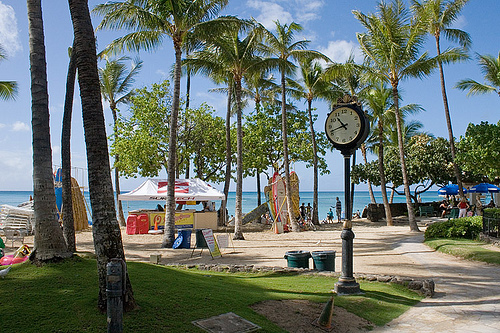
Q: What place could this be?
A: It is a park.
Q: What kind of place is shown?
A: It is a park.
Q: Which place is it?
A: It is a park.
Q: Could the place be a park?
A: Yes, it is a park.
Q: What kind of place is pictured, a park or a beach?
A: It is a park.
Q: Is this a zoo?
A: No, it is a park.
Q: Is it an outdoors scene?
A: Yes, it is outdoors.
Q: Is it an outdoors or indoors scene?
A: It is outdoors.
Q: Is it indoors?
A: No, it is outdoors.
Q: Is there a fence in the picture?
A: No, there are no fences.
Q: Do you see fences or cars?
A: No, there are no fences or cars.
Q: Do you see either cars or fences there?
A: No, there are no fences or cars.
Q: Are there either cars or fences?
A: No, there are no fences or cars.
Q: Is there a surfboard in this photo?
A: Yes, there is a surfboard.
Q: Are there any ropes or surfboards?
A: Yes, there is a surfboard.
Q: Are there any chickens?
A: No, there are no chickens.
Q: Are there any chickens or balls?
A: No, there are no chickens or balls.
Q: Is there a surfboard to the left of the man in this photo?
A: Yes, there is a surfboard to the left of the man.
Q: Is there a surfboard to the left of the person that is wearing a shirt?
A: Yes, there is a surfboard to the left of the man.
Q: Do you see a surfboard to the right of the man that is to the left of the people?
A: No, the surfboard is to the left of the man.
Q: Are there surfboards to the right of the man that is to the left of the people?
A: No, the surfboard is to the left of the man.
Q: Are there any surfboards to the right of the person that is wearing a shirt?
A: No, the surfboard is to the left of the man.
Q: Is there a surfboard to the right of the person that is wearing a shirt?
A: No, the surfboard is to the left of the man.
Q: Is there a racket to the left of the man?
A: No, there is a surfboard to the left of the man.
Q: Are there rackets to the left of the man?
A: No, there is a surfboard to the left of the man.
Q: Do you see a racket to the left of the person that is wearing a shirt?
A: No, there is a surfboard to the left of the man.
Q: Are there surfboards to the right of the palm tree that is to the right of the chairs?
A: Yes, there is a surfboard to the right of the palm tree.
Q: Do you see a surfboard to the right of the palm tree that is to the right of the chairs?
A: Yes, there is a surfboard to the right of the palm tree.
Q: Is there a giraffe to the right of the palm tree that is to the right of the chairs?
A: No, there is a surfboard to the right of the palm tree.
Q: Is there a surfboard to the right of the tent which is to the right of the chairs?
A: Yes, there is a surfboard to the right of the tent.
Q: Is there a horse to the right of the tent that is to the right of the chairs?
A: No, there is a surfboard to the right of the tent.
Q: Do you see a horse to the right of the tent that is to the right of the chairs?
A: No, there is a surfboard to the right of the tent.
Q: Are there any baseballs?
A: No, there are no baseballs.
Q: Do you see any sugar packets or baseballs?
A: No, there are no baseballs or sugar packets.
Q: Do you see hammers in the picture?
A: No, there are no hammers.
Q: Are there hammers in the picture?
A: No, there are no hammers.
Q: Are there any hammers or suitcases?
A: No, there are no hammers or suitcases.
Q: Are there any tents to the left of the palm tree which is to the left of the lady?
A: Yes, there is a tent to the left of the palm tree.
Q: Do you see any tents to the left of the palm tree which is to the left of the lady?
A: Yes, there is a tent to the left of the palm tree.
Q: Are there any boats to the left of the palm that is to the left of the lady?
A: No, there is a tent to the left of the palm.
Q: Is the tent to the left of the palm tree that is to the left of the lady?
A: Yes, the tent is to the left of the palm.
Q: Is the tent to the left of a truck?
A: No, the tent is to the left of the palm.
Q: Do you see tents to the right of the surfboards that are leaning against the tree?
A: Yes, there is a tent to the right of the surfboards.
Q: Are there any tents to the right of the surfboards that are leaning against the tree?
A: Yes, there is a tent to the right of the surfboards.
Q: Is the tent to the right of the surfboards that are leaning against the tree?
A: Yes, the tent is to the right of the surfboards.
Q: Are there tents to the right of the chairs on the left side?
A: Yes, there is a tent to the right of the chairs.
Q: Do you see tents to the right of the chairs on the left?
A: Yes, there is a tent to the right of the chairs.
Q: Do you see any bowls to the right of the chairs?
A: No, there is a tent to the right of the chairs.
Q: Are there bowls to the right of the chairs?
A: No, there is a tent to the right of the chairs.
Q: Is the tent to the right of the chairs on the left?
A: Yes, the tent is to the right of the chairs.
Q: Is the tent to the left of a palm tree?
A: Yes, the tent is to the left of a palm tree.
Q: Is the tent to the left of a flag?
A: No, the tent is to the left of a palm tree.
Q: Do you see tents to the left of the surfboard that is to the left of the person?
A: Yes, there is a tent to the left of the surf board.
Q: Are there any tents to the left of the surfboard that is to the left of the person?
A: Yes, there is a tent to the left of the surf board.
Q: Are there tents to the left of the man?
A: Yes, there is a tent to the left of the man.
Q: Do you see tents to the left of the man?
A: Yes, there is a tent to the left of the man.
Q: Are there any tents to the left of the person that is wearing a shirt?
A: Yes, there is a tent to the left of the man.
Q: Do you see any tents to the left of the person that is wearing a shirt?
A: Yes, there is a tent to the left of the man.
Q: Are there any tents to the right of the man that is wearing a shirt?
A: No, the tent is to the left of the man.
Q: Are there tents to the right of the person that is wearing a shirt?
A: No, the tent is to the left of the man.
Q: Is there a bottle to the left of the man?
A: No, there is a tent to the left of the man.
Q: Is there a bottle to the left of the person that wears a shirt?
A: No, there is a tent to the left of the man.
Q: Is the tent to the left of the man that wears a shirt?
A: Yes, the tent is to the left of the man.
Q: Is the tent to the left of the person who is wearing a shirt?
A: Yes, the tent is to the left of the man.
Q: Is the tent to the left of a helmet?
A: No, the tent is to the left of the man.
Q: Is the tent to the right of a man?
A: No, the tent is to the left of a man.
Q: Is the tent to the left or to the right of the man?
A: The tent is to the left of the man.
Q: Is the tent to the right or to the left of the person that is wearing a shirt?
A: The tent is to the left of the man.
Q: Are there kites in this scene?
A: No, there are no kites.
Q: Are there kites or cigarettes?
A: No, there are no kites or cigarettes.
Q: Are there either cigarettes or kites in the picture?
A: No, there are no kites or cigarettes.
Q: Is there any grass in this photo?
A: Yes, there is grass.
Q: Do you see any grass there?
A: Yes, there is grass.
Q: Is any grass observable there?
A: Yes, there is grass.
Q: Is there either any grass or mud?
A: Yes, there is grass.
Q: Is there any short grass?
A: Yes, there is short grass.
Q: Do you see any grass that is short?
A: Yes, there is grass that is short.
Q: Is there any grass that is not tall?
A: Yes, there is short grass.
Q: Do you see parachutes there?
A: No, there are no parachutes.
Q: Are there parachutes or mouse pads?
A: No, there are no parachutes or mouse pads.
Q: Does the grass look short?
A: Yes, the grass is short.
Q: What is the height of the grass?
A: The grass is short.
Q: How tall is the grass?
A: The grass is short.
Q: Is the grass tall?
A: No, the grass is short.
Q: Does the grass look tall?
A: No, the grass is short.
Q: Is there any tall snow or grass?
A: No, there is grass but it is short.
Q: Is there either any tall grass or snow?
A: No, there is grass but it is short.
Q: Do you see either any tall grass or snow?
A: No, there is grass but it is short.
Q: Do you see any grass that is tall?
A: No, there is grass but it is short.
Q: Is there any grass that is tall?
A: No, there is grass but it is short.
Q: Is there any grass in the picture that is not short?
A: No, there is grass but it is short.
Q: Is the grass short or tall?
A: The grass is short.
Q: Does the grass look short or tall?
A: The grass is short.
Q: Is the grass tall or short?
A: The grass is short.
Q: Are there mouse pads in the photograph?
A: No, there are no mouse pads.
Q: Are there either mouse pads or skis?
A: No, there are no mouse pads or skis.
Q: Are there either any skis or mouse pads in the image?
A: No, there are no mouse pads or skis.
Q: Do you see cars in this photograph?
A: No, there are no cars.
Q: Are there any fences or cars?
A: No, there are no cars or fences.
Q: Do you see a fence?
A: No, there are no fences.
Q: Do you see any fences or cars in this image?
A: No, there are no fences or cars.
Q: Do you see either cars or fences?
A: No, there are no fences or cars.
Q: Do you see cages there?
A: No, there are no cages.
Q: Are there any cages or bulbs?
A: No, there are no cages or bulbs.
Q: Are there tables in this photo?
A: No, there are no tables.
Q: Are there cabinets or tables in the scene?
A: No, there are no tables or cabinets.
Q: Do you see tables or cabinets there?
A: No, there are no tables or cabinets.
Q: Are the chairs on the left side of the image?
A: Yes, the chairs are on the left of the image.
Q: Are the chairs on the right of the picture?
A: No, the chairs are on the left of the image.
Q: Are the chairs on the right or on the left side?
A: The chairs are on the left of the image.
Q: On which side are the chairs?
A: The chairs are on the left of the image.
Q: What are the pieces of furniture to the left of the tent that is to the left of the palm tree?
A: The pieces of furniture are chairs.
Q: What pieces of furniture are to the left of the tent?
A: The pieces of furniture are chairs.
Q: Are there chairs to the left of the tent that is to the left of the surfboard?
A: Yes, there are chairs to the left of the tent.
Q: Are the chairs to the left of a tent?
A: Yes, the chairs are to the left of a tent.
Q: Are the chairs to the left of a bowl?
A: No, the chairs are to the left of a tent.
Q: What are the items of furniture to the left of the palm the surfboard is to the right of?
A: The pieces of furniture are chairs.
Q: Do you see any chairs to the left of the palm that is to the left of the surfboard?
A: Yes, there are chairs to the left of the palm tree.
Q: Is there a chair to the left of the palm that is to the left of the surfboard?
A: Yes, there are chairs to the left of the palm tree.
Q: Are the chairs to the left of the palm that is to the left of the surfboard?
A: Yes, the chairs are to the left of the palm tree.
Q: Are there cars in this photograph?
A: No, there are no cars.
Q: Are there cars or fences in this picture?
A: No, there are no cars or fences.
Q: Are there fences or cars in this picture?
A: No, there are no cars or fences.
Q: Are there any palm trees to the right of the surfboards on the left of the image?
A: Yes, there are palm trees to the right of the surfboards.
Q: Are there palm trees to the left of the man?
A: Yes, there are palm trees to the left of the man.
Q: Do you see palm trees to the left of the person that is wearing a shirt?
A: Yes, there are palm trees to the left of the man.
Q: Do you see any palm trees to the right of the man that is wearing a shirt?
A: No, the palm trees are to the left of the man.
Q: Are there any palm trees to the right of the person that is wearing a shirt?
A: No, the palm trees are to the left of the man.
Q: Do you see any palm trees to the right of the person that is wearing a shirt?
A: No, the palm trees are to the left of the man.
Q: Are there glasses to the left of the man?
A: No, there are palm trees to the left of the man.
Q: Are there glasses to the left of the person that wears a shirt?
A: No, there are palm trees to the left of the man.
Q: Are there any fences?
A: No, there are no fences.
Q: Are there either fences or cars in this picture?
A: No, there are no fences or cars.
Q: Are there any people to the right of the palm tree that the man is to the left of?
A: Yes, there are people to the right of the palm tree.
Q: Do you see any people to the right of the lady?
A: Yes, there are people to the right of the lady.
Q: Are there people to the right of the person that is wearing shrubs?
A: Yes, there are people to the right of the lady.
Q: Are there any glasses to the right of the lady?
A: No, there are people to the right of the lady.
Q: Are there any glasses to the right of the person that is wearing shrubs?
A: No, there are people to the right of the lady.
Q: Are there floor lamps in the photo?
A: No, there are no floor lamps.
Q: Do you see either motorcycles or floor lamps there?
A: No, there are no floor lamps or motorcycles.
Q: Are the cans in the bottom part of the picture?
A: Yes, the cans are in the bottom of the image.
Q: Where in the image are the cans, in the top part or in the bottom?
A: The cans are in the bottom of the image.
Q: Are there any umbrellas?
A: Yes, there is an umbrella.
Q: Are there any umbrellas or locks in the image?
A: Yes, there is an umbrella.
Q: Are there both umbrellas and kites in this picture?
A: No, there is an umbrella but no kites.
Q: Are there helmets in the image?
A: No, there are no helmets.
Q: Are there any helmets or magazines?
A: No, there are no helmets or magazines.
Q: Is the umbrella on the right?
A: Yes, the umbrella is on the right of the image.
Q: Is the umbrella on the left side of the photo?
A: No, the umbrella is on the right of the image.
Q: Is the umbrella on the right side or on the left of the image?
A: The umbrella is on the right of the image.